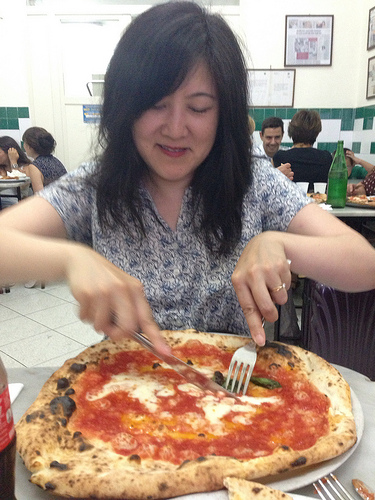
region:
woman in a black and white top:
[78, 10, 270, 347]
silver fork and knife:
[115, 281, 295, 399]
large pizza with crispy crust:
[24, 328, 339, 496]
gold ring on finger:
[272, 265, 296, 319]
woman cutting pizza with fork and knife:
[63, 141, 321, 405]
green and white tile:
[252, 105, 361, 152]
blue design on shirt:
[274, 207, 284, 217]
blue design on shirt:
[260, 188, 270, 203]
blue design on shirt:
[266, 173, 276, 182]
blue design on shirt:
[68, 202, 81, 215]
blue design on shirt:
[127, 257, 136, 270]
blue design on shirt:
[123, 237, 138, 248]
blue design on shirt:
[160, 301, 173, 314]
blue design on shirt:
[208, 303, 220, 316]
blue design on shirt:
[207, 261, 218, 273]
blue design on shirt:
[158, 236, 173, 249]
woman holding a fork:
[218, 272, 301, 394]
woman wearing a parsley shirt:
[49, 167, 299, 333]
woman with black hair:
[99, 6, 257, 210]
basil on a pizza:
[246, 367, 281, 399]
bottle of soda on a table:
[0, 353, 21, 497]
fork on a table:
[301, 471, 336, 497]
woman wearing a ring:
[264, 276, 295, 295]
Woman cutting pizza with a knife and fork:
[0, 0, 372, 499]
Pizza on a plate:
[15, 328, 365, 497]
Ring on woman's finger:
[270, 282, 287, 295]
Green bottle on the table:
[327, 137, 350, 211]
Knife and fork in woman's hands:
[66, 226, 291, 402]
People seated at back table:
[259, 110, 373, 185]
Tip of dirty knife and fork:
[311, 469, 373, 499]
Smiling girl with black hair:
[88, 0, 258, 257]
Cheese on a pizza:
[87, 358, 269, 434]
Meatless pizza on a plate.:
[14, 329, 357, 499]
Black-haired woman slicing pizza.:
[0, 0, 374, 355]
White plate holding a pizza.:
[167, 332, 364, 499]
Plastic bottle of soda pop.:
[0, 358, 17, 499]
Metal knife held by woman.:
[105, 310, 236, 397]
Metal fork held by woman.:
[224, 258, 290, 395]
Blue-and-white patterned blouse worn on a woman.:
[35, 134, 316, 337]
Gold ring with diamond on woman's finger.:
[268, 283, 285, 292]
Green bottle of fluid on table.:
[325, 140, 349, 207]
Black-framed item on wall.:
[284, 15, 334, 66]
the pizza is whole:
[15, 327, 359, 496]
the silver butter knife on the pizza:
[102, 308, 241, 401]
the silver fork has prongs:
[223, 310, 265, 395]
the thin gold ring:
[269, 281, 286, 294]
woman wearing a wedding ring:
[270, 280, 289, 295]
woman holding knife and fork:
[92, 297, 279, 400]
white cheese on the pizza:
[192, 387, 257, 428]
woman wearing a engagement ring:
[267, 277, 289, 302]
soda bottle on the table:
[0, 354, 20, 498]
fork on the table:
[312, 471, 347, 498]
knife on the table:
[349, 473, 372, 498]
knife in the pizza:
[89, 299, 248, 412]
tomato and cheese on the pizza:
[77, 340, 285, 453]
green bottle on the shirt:
[324, 135, 351, 214]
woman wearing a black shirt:
[273, 142, 331, 176]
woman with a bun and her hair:
[19, 122, 56, 162]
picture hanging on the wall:
[280, 13, 336, 71]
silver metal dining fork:
[220, 338, 265, 400]